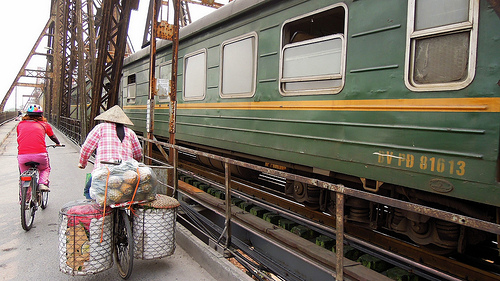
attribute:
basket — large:
[58, 199, 116, 279]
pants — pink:
[17, 151, 54, 199]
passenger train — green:
[114, 0, 496, 277]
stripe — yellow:
[121, 100, 497, 118]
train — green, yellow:
[116, 22, 485, 220]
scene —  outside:
[0, 8, 238, 267]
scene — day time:
[0, 68, 217, 270]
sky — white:
[1, 3, 35, 43]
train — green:
[121, 4, 499, 271]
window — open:
[277, 1, 351, 101]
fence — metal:
[197, 159, 431, 279]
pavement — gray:
[48, 143, 77, 197]